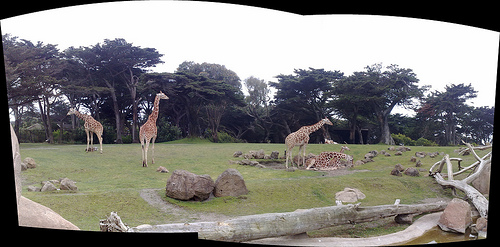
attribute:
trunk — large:
[104, 195, 477, 242]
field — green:
[17, 143, 492, 243]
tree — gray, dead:
[169, 74, 301, 138]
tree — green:
[421, 81, 477, 138]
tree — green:
[339, 66, 414, 143]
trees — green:
[3, 30, 494, 148]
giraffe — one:
[262, 109, 379, 171]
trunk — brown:
[41, 109, 56, 144]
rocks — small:
[25, 176, 77, 193]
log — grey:
[204, 179, 451, 241]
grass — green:
[20, 140, 483, 240]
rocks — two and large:
[164, 168, 254, 197]